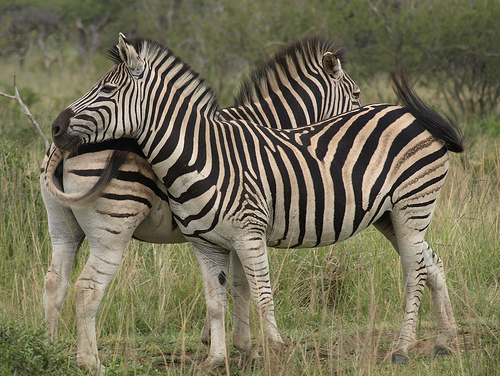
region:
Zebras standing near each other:
[42, 31, 460, 372]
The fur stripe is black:
[332, 162, 345, 232]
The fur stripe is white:
[305, 179, 314, 242]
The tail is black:
[387, 70, 464, 153]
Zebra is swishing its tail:
[390, 71, 463, 153]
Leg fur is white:
[48, 204, 76, 257]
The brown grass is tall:
[285, 260, 377, 365]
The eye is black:
[102, 84, 112, 94]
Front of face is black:
[52, 109, 79, 151]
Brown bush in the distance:
[428, 47, 496, 117]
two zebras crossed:
[14, 27, 474, 367]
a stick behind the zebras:
[0, 73, 55, 158]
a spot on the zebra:
[215, 268, 227, 290]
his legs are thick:
[7, 217, 146, 369]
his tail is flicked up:
[387, 64, 473, 159]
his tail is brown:
[385, 63, 470, 163]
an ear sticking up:
[319, 51, 354, 83]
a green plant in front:
[5, 322, 75, 374]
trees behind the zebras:
[7, 0, 482, 80]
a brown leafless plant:
[405, 34, 499, 121]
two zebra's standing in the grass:
[23, 16, 473, 370]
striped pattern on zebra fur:
[241, 144, 373, 217]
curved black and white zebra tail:
[45, 137, 136, 209]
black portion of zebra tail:
[380, 65, 471, 159]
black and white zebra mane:
[104, 34, 226, 119]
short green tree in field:
[386, 4, 498, 138]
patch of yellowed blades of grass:
[302, 270, 394, 374]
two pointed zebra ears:
[109, 27, 146, 74]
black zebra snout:
[38, 103, 89, 155]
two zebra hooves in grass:
[388, 329, 464, 366]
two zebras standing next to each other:
[7, 11, 496, 373]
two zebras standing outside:
[32, 35, 471, 366]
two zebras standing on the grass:
[0, 16, 494, 323]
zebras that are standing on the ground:
[14, 17, 487, 372]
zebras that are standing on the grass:
[11, 23, 486, 375]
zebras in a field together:
[4, 23, 499, 342]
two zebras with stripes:
[37, 20, 498, 345]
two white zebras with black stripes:
[30, 6, 480, 352]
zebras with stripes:
[13, 15, 484, 360]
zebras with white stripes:
[28, 16, 493, 337]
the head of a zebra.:
[38, 25, 208, 204]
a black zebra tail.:
[368, 64, 477, 167]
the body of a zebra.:
[249, 100, 380, 272]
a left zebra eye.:
[93, 77, 125, 105]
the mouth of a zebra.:
[40, 98, 107, 153]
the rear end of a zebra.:
[378, 92, 460, 254]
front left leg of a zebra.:
[218, 213, 291, 373]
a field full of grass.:
[0, 7, 497, 372]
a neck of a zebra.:
[153, 77, 245, 205]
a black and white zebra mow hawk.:
[108, 28, 235, 128]